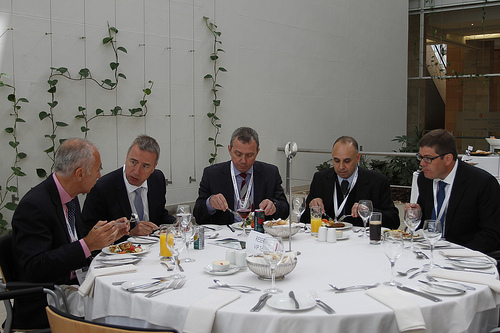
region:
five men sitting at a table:
[2, 122, 499, 319]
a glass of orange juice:
[153, 220, 181, 262]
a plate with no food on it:
[257, 285, 339, 323]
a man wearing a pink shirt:
[11, 133, 113, 310]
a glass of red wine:
[232, 193, 254, 237]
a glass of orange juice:
[305, 202, 325, 241]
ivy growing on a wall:
[1, 20, 228, 132]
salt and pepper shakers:
[315, 224, 340, 247]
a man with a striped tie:
[194, 123, 288, 223]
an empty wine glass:
[420, 215, 450, 267]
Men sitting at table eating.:
[192, 120, 491, 258]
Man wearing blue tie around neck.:
[431, 179, 456, 219]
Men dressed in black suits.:
[7, 103, 173, 320]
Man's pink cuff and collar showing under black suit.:
[49, 172, 91, 269]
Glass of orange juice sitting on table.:
[306, 198, 324, 238]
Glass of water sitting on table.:
[175, 201, 195, 248]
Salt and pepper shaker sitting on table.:
[316, 220, 341, 247]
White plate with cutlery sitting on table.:
[246, 283, 343, 326]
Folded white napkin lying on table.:
[361, 283, 431, 329]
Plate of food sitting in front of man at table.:
[102, 237, 156, 261]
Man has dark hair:
[326, 131, 361, 153]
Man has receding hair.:
[325, 127, 368, 166]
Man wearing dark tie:
[332, 174, 358, 210]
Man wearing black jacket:
[304, 162, 401, 230]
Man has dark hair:
[418, 127, 460, 161]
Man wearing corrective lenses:
[410, 146, 451, 163]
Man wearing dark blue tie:
[431, 179, 451, 219]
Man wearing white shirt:
[424, 166, 469, 227]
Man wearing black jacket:
[406, 165, 497, 237]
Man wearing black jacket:
[189, 159, 291, 229]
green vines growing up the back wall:
[2, 35, 254, 200]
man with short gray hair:
[7, 120, 122, 301]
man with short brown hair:
[192, 98, 309, 241]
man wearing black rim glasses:
[407, 111, 479, 233]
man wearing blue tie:
[387, 126, 484, 253]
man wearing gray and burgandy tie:
[183, 87, 305, 252]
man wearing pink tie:
[7, 117, 105, 299]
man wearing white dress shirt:
[85, 136, 182, 243]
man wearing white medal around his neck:
[195, 86, 295, 268]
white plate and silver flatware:
[240, 281, 350, 322]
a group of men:
[19, 61, 499, 299]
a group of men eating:
[12, 80, 499, 299]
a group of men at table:
[32, 17, 499, 328]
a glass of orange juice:
[128, 213, 198, 263]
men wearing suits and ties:
[9, 75, 499, 325]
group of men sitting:
[33, 89, 494, 266]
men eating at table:
[18, 82, 480, 272]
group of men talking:
[5, 63, 496, 257]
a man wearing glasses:
[383, 110, 498, 237]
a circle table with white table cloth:
[122, 206, 482, 331]